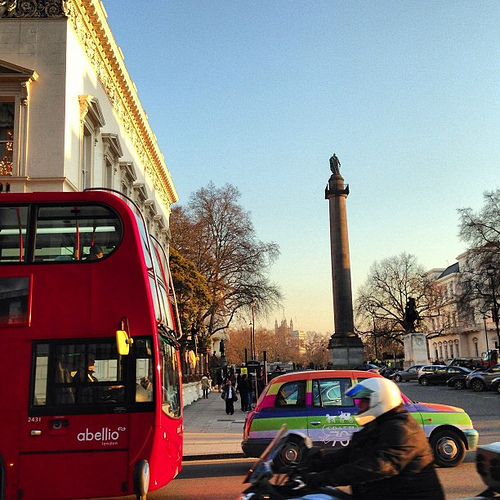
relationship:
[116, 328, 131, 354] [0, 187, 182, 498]
mirror on side of bus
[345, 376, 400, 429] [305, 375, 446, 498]
helmet on head of person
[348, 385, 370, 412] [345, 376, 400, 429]
visor on a helmet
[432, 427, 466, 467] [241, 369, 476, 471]
front wheel of car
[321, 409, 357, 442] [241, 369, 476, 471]
name on side of car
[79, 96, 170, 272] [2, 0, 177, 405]
windows on a building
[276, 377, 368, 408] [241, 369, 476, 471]
side windows on a car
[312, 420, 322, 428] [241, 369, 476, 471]
door handle of a car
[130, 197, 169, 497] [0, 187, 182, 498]
edge of bus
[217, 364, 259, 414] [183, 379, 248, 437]
people on sidewalk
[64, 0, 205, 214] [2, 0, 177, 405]
border on top of building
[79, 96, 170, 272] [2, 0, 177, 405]
windows along side of building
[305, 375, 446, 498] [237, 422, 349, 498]
person on a motorbike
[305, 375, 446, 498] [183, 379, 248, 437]
person walking on sidewalk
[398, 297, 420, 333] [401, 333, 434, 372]
statue on a white pedestal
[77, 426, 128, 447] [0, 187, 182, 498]
writing on bus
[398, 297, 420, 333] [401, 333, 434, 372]
statue on a pedestal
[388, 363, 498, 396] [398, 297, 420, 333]
cars parked by statue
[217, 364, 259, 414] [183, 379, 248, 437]
people walking on sidewalk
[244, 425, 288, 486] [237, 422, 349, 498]
windshield on motorbike